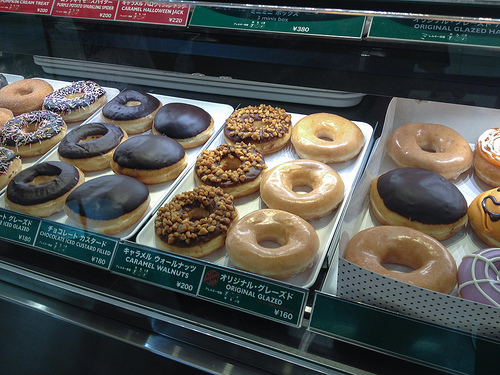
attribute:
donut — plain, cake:
[0, 77, 53, 118]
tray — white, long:
[140, 99, 375, 293]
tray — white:
[6, 84, 238, 256]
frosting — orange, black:
[471, 188, 499, 241]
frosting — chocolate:
[64, 173, 149, 221]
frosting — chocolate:
[112, 133, 186, 168]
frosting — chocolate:
[156, 102, 209, 138]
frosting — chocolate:
[9, 161, 81, 199]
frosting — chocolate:
[58, 121, 123, 158]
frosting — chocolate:
[46, 81, 104, 112]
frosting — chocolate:
[3, 112, 69, 146]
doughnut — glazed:
[226, 208, 325, 287]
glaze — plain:
[226, 207, 329, 281]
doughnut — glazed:
[254, 155, 354, 223]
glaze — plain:
[260, 158, 348, 225]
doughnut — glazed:
[292, 108, 366, 170]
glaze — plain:
[291, 109, 370, 168]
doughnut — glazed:
[387, 117, 479, 182]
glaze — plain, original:
[388, 121, 475, 169]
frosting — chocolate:
[154, 188, 237, 245]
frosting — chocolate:
[195, 143, 266, 187]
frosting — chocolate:
[228, 107, 292, 141]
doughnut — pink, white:
[455, 243, 499, 312]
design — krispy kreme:
[336, 266, 498, 340]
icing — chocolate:
[114, 134, 183, 165]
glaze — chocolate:
[102, 89, 158, 117]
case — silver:
[2, 4, 498, 372]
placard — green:
[187, 3, 370, 45]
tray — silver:
[27, 38, 380, 117]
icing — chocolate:
[228, 107, 289, 139]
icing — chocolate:
[45, 81, 102, 109]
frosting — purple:
[453, 244, 499, 319]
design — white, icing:
[460, 245, 498, 305]